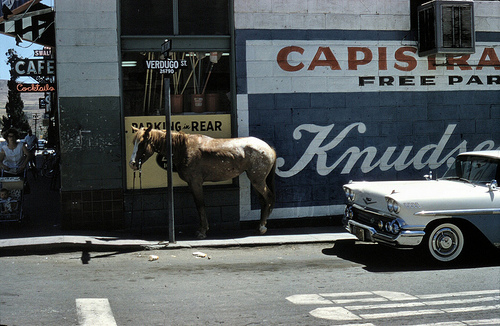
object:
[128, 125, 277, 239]
horse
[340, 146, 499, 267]
car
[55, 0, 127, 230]
wall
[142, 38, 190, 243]
sign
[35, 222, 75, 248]
sidewalk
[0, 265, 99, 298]
street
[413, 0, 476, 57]
air conditioner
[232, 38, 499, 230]
advertisement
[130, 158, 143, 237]
rein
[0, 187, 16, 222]
child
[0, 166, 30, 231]
stroller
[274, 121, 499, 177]
letter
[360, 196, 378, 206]
logo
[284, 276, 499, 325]
pavement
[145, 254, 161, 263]
trash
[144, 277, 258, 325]
road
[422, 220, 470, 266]
tire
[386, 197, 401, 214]
headlight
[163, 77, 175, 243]
pole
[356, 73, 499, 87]
writing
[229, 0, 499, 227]
wall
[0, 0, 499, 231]
"building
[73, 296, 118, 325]
"line